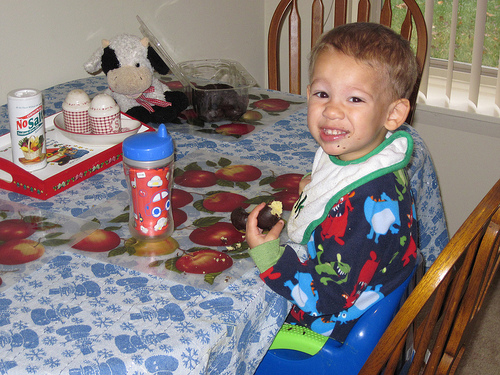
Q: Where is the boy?
A: In a chair.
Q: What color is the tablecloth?
A: Blue and white.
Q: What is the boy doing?
A: Eating.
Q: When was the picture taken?
A: Daytime.